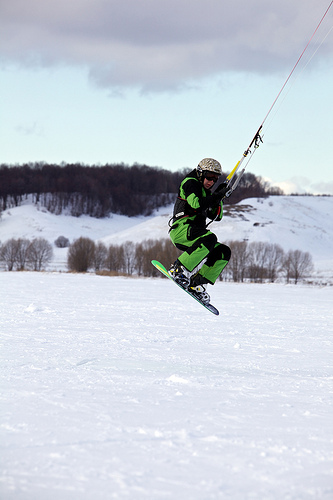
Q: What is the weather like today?
A: It is cloudy.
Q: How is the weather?
A: It is cloudy.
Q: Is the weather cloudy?
A: Yes, it is cloudy.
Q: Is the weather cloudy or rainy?
A: It is cloudy.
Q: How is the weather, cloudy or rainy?
A: It is cloudy.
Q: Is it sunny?
A: No, it is cloudy.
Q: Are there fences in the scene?
A: No, there are no fences.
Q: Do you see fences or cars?
A: No, there are no fences or cars.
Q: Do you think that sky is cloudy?
A: Yes, the sky is cloudy.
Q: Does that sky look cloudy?
A: Yes, the sky is cloudy.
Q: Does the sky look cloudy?
A: Yes, the sky is cloudy.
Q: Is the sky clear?
A: No, the sky is cloudy.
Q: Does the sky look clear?
A: No, the sky is cloudy.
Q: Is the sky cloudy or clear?
A: The sky is cloudy.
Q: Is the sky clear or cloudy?
A: The sky is cloudy.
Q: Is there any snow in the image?
A: Yes, there is snow.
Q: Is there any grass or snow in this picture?
A: Yes, there is snow.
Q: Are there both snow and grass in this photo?
A: No, there is snow but no grass.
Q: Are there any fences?
A: No, there are no fences.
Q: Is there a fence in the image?
A: No, there are no fences.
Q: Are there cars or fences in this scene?
A: No, there are no fences or cars.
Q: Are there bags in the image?
A: No, there are no bags.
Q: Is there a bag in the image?
A: No, there are no bags.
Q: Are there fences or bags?
A: No, there are no bags or fences.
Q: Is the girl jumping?
A: Yes, the girl is jumping.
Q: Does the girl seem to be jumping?
A: Yes, the girl is jumping.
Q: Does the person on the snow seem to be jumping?
A: Yes, the girl is jumping.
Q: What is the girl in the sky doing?
A: The girl is jumping.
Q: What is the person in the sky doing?
A: The girl is jumping.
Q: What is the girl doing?
A: The girl is jumping.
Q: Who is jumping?
A: The girl is jumping.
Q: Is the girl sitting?
A: No, the girl is jumping.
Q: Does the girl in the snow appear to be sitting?
A: No, the girl is jumping.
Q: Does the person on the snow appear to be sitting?
A: No, the girl is jumping.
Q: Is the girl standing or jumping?
A: The girl is jumping.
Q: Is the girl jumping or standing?
A: The girl is jumping.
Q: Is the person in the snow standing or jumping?
A: The girl is jumping.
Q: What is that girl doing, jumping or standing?
A: The girl is jumping.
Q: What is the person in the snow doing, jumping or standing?
A: The girl is jumping.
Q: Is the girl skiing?
A: Yes, the girl is skiing.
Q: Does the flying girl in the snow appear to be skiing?
A: Yes, the girl is skiing.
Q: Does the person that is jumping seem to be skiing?
A: Yes, the girl is skiing.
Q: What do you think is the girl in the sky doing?
A: The girl is skiing.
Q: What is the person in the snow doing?
A: The girl is skiing.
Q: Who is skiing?
A: The girl is skiing.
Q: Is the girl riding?
A: No, the girl is skiing.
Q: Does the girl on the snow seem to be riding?
A: No, the girl is skiing.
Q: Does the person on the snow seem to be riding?
A: No, the girl is skiing.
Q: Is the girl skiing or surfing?
A: The girl is skiing.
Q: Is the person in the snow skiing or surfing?
A: The girl is skiing.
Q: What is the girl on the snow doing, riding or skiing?
A: The girl is skiing.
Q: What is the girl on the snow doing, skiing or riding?
A: The girl is skiing.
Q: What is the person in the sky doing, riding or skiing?
A: The girl is skiing.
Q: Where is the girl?
A: The girl is on the snow.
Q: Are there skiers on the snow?
A: No, there is a girl on the snow.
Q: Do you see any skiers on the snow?
A: No, there is a girl on the snow.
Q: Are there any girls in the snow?
A: Yes, there is a girl in the snow.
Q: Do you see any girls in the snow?
A: Yes, there is a girl in the snow.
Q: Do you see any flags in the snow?
A: No, there is a girl in the snow.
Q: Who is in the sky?
A: The girl is in the sky.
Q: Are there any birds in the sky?
A: No, there is a girl in the sky.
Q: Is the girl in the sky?
A: Yes, the girl is in the sky.